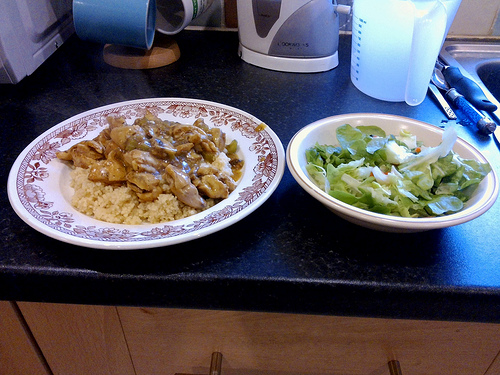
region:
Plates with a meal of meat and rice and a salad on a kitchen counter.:
[5, 46, 493, 268]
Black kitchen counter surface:
[2, 30, 497, 321]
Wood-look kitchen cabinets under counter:
[1, 301, 494, 373]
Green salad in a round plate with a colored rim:
[287, 110, 497, 230]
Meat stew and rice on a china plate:
[7, 96, 284, 250]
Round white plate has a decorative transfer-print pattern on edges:
[8, 96, 288, 250]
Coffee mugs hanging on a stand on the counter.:
[66, 0, 200, 72]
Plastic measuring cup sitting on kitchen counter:
[347, 0, 460, 110]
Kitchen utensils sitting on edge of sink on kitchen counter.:
[430, 53, 497, 140]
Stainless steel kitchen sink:
[441, 40, 498, 137]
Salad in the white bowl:
[287, 113, 499, 230]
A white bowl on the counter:
[285, 110, 497, 230]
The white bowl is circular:
[291, 112, 496, 228]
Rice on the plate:
[73, 168, 179, 223]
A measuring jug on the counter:
[349, 0, 458, 105]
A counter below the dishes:
[0, 40, 497, 322]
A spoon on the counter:
[433, 68, 494, 131]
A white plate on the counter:
[7, 96, 282, 248]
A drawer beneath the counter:
[118, 309, 498, 374]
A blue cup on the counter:
[73, 0, 156, 47]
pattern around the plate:
[132, 229, 200, 239]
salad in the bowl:
[325, 142, 445, 217]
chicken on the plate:
[117, 140, 224, 195]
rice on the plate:
[100, 180, 186, 214]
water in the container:
[332, 8, 445, 105]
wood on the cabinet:
[150, 331, 304, 364]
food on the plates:
[15, 148, 465, 266]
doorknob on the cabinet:
[183, 350, 242, 373]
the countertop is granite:
[258, 87, 306, 109]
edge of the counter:
[381, 276, 482, 322]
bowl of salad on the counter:
[286, 92, 489, 247]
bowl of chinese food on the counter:
[55, 112, 221, 218]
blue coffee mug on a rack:
[68, 4, 155, 74]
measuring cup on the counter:
[345, 2, 450, 102]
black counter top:
[286, 232, 493, 282]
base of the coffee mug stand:
[97, 39, 183, 72]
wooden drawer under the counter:
[138, 319, 439, 371]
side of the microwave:
[11, 15, 60, 66]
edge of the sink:
[468, 43, 499, 119]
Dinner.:
[4, 89, 286, 254]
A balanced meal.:
[3, 87, 498, 247]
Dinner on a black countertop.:
[0, 1, 499, 326]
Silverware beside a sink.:
[423, 53, 498, 138]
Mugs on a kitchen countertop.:
[62, 0, 212, 75]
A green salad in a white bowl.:
[287, 101, 498, 237]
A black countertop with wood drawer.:
[0, 259, 499, 366]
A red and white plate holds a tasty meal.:
[2, 79, 287, 264]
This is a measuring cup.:
[346, 0, 457, 107]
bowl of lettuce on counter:
[280, 103, 497, 233]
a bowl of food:
[290, 107, 498, 224]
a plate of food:
[10, 97, 270, 242]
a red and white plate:
[10, 95, 275, 245]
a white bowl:
[286, 110, 482, 225]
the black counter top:
[2, 15, 497, 311]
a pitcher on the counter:
[350, 5, 431, 100]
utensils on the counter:
[430, 51, 480, 131]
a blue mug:
[66, 0, 151, 45]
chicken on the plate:
[160, 160, 206, 205]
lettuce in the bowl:
[315, 158, 395, 203]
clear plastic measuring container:
[348, 2, 461, 104]